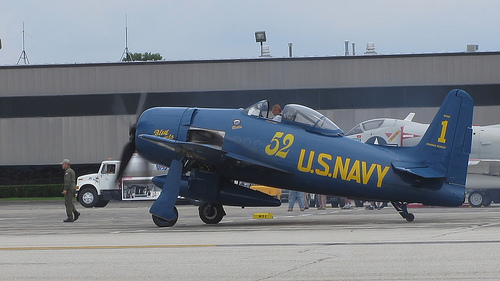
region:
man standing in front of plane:
[60, 156, 83, 223]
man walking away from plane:
[57, 155, 81, 223]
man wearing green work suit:
[60, 160, 76, 223]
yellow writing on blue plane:
[264, 129, 296, 161]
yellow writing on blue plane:
[296, 146, 390, 190]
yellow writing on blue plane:
[436, 117, 450, 144]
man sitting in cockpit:
[270, 100, 285, 124]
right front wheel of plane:
[197, 204, 226, 223]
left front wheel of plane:
[147, 205, 175, 227]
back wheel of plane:
[403, 213, 415, 224]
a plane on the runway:
[121, 83, 475, 226]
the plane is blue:
[123, 83, 478, 235]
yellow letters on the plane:
[295, 144, 387, 194]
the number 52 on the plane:
[259, 129, 295, 159]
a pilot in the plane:
[263, 99, 285, 125]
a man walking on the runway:
[55, 155, 84, 225]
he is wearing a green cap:
[50, 158, 75, 165]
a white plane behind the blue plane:
[340, 109, 497, 208]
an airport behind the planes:
[1, 41, 495, 208]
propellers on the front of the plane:
[108, 80, 148, 185]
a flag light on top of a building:
[256, 34, 266, 40]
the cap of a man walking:
[62, 158, 69, 164]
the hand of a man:
[61, 190, 66, 195]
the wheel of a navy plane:
[199, 203, 221, 220]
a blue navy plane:
[148, 110, 301, 165]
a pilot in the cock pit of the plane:
[271, 107, 278, 118]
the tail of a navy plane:
[448, 90, 470, 165]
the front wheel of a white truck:
[82, 189, 97, 206]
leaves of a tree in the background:
[141, 52, 158, 59]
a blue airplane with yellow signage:
[90, 64, 473, 223]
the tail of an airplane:
[426, 89, 483, 213]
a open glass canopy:
[245, 93, 347, 135]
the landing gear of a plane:
[147, 165, 232, 230]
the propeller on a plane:
[102, 78, 149, 183]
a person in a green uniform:
[49, 157, 88, 234]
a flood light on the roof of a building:
[246, 24, 274, 69]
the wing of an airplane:
[149, 131, 261, 169]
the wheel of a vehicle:
[77, 185, 99, 206]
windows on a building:
[5, 155, 60, 184]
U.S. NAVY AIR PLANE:
[101, 69, 483, 237]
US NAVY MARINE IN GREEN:
[44, 145, 99, 232]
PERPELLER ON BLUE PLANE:
[93, 72, 170, 211]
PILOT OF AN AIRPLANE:
[239, 74, 484, 226]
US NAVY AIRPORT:
[15, 41, 490, 253]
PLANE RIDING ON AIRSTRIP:
[12, 53, 496, 264]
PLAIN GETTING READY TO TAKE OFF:
[46, 75, 496, 271]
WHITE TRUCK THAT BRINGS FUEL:
[59, 105, 234, 238]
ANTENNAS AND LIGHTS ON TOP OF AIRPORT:
[13, 29, 490, 72]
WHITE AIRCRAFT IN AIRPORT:
[320, 77, 499, 231]